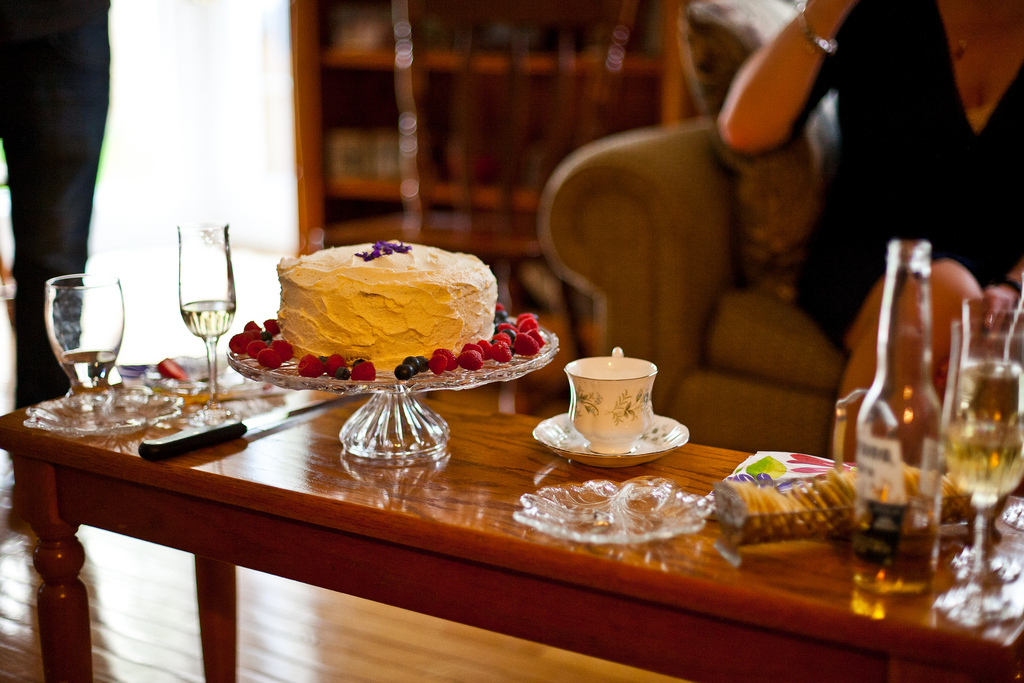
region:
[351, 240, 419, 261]
Violet toppings on top of cake.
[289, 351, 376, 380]
Different kind of berries.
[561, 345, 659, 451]
A white tea cup with designs.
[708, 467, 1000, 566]
A long tray of cookies.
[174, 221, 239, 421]
A clear tall glass with wine.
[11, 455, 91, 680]
A wooden and brown foot of a table.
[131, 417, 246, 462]
A black handle of knife.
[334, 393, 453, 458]
A celar base of the cake plate.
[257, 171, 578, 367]
a cake on a table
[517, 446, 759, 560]
a ashtray on a table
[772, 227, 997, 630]
a beer bottle on a table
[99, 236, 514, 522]
a knife on a table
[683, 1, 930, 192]
the arm of a person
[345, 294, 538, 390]
strawberries near a cake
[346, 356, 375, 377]
Red raspberry around the white cake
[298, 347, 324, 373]
Red raspberry around the white cake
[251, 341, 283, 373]
Red raspberry around the white cake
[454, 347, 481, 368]
Red raspberry around the white cake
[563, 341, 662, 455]
Teacup sitting on the plate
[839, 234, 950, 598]
Beer bottle next to the champagne flute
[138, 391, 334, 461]
Knife next to the glass cake stand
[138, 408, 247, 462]
Black handle of the knife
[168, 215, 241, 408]
Champagne flute next to the white cake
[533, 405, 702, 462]
A tea saucer.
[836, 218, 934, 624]
A beer bottle.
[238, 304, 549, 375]
Berries surrounding a cake.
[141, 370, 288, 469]
A black handled knife.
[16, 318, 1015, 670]
A wooden coffee table.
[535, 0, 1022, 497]
A person sitting on a sofa.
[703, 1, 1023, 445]
A woman in a black dress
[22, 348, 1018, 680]
A long wooden table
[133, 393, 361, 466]
A knife on a table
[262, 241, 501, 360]
A vanilla cake with blueberries on the top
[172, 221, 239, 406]
A wine glass on a table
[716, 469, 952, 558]
Crackers on a table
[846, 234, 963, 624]
A beer on a table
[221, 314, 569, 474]
A crystal cake holder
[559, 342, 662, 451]
A beige floral tea cup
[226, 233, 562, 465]
cake surrounded by berries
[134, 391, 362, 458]
knife sitting on a table next to the cake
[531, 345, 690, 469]
tea cup and saucer on the table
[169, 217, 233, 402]
partially filled wine glass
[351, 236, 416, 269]
small purple garnish on the top of a cake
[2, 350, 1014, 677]
long skinny table full of food and drink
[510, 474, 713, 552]
glass dish on the table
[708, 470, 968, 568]
tray of crackers on the table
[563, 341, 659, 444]
a green and white coffee mug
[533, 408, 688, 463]
a small plate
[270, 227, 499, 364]
a white iced cake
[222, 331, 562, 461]
a glass cake plate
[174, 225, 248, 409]
a tall wine glass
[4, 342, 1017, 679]
a long wooden table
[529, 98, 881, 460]
the side of a couch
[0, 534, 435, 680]
brown hardwood floor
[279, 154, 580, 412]
food on the plate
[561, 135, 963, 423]
a green sofa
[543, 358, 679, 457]
a white tea cup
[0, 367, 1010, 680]
a wooden coffee table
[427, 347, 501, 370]
raspberries on the platter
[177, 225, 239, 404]
a wine glass on the table